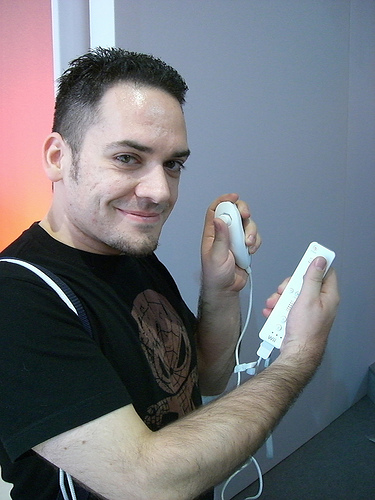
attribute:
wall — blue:
[178, 3, 366, 418]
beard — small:
[97, 231, 158, 254]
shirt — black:
[15, 218, 236, 418]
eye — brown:
[110, 153, 144, 165]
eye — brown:
[164, 161, 183, 171]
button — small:
[217, 212, 232, 225]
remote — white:
[265, 234, 345, 370]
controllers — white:
[211, 199, 252, 271]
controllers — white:
[257, 238, 336, 349]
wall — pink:
[3, 0, 52, 221]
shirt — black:
[115, 334, 154, 399]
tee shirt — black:
[90, 276, 167, 347]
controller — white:
[256, 238, 339, 367]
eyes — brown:
[101, 142, 198, 177]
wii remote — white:
[213, 201, 336, 366]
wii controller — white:
[264, 233, 336, 361]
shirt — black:
[23, 239, 190, 423]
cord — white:
[241, 267, 264, 372]